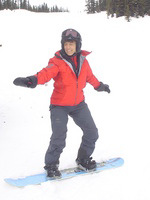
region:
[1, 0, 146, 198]
The woman is outside on a snowy day.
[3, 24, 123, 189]
The woman is standing on a snowboard.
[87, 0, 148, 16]
Pine trees are in the background.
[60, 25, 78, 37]
Goggles are pushed up on the woman's head.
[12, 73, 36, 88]
The woman has a black glove on her hand.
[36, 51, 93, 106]
The woman is wearing a red jacket.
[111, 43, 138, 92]
Snow is on the ground.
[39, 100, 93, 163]
The woman is wearing black snow pants.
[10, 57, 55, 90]
The woman is extending her arm.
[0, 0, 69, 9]
The trees are green.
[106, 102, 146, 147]
The snow is the color white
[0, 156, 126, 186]
The woman is standing on a snowboard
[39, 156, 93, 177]
The feet of the woman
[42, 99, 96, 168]
The woman has on gray pants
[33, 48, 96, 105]
The woman has on an orange pants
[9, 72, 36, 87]
The woman has on black gloves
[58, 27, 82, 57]
The head of the woman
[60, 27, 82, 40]
The snow goggles on the woman's head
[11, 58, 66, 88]
The arm of the woman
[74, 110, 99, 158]
The leg of the woman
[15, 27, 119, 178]
the person on the snowboard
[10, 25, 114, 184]
the person is snowboarding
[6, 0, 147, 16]
pine trees at the top of the slope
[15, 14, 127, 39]
the snow covered ground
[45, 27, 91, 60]
the helmet on the head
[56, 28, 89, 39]
goggles on the helmet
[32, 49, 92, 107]
the person wearing red jacket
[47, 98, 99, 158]
the person wearing blue pants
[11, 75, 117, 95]
the gloves on the hands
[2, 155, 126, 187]
the snowboard is blue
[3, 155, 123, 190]
Blue snowboard on the snow.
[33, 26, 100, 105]
Red jacket on person.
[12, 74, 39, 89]
Black glove on hand.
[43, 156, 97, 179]
Black boots on person.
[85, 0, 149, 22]
Trees in the background.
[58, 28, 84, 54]
Goggles on the person's head.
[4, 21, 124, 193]
Person snowboarding on the snow.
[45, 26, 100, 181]
Grey pants on person.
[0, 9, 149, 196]
White snow covering the ground.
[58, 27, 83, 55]
Black helmet on head.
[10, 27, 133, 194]
Woman snowboarding in the snow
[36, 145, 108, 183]
Woman wearing snow boots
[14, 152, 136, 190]
The snowboard is thin and blue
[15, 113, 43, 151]
The snow is smooth and white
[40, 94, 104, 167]
Woman wearing snow pants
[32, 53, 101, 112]
Woman wearing a red jacket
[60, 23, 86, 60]
Woman wearing a helmet and goggles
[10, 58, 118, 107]
Woman has her arms out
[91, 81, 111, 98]
Woman wearing gloves on hands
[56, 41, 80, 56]
Woman is smiling